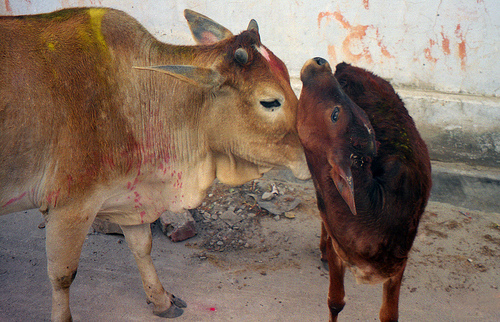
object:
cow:
[0, 6, 312, 320]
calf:
[296, 56, 434, 320]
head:
[295, 54, 379, 181]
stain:
[258, 46, 284, 80]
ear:
[328, 153, 359, 218]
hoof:
[326, 299, 347, 315]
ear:
[182, 7, 235, 45]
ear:
[132, 63, 223, 88]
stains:
[141, 140, 172, 166]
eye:
[330, 104, 341, 123]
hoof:
[149, 300, 184, 317]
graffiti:
[315, 0, 470, 65]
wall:
[0, 1, 500, 173]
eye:
[258, 100, 282, 109]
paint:
[38, 6, 114, 79]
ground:
[1, 177, 500, 321]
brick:
[157, 206, 198, 243]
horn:
[247, 18, 259, 32]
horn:
[233, 48, 251, 64]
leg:
[44, 208, 97, 321]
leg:
[117, 221, 186, 318]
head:
[200, 29, 312, 181]